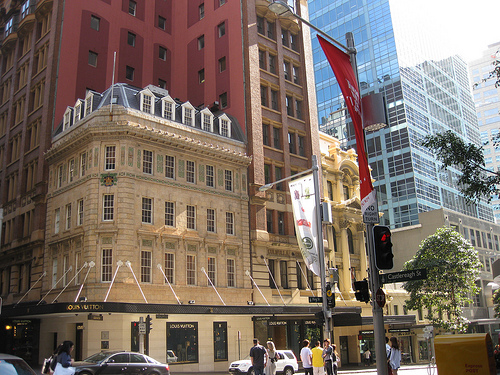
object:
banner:
[288, 173, 332, 282]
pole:
[313, 156, 338, 375]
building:
[307, 1, 500, 257]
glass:
[314, 3, 395, 206]